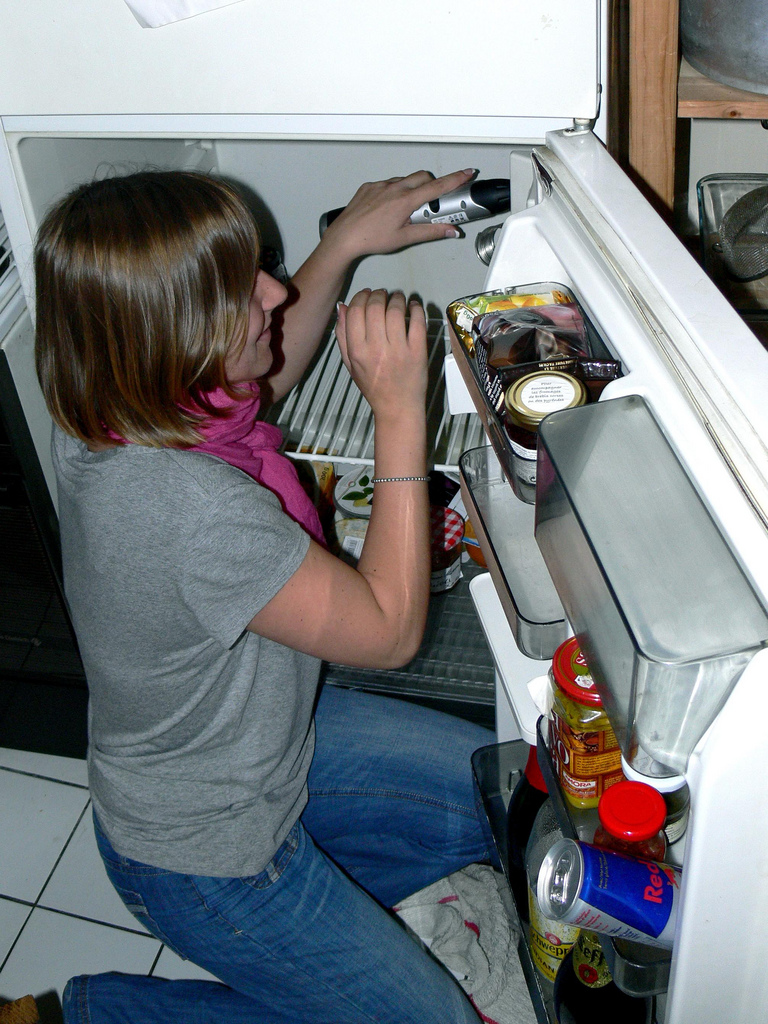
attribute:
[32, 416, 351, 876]
shirt — grey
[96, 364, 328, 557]
scarf — pink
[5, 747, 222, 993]
tile — white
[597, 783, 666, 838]
lid — red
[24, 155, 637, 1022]
woman — gray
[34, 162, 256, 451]
hair — brown